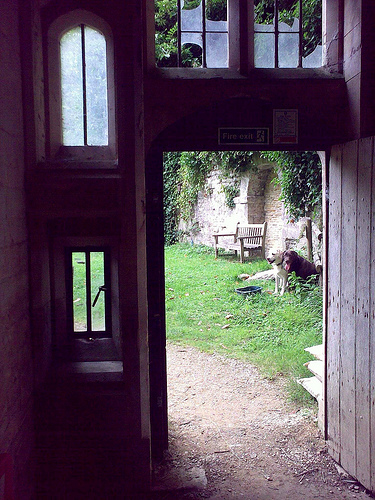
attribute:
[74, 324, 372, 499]
path — dirt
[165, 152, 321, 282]
wall — brick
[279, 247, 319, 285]
dog — brown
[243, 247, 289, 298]
dog — white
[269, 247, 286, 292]
dog — black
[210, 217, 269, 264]
bench — wooden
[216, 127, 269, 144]
sign — fire exit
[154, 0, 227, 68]
glass — broken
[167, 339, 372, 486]
path — dirt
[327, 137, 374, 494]
structure — wood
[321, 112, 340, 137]
ground — closed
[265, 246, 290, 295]
canine — white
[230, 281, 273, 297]
container — black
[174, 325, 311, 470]
path — dirt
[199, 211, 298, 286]
bench — wooden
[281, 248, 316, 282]
canine — dark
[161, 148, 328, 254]
plant — green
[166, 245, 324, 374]
terrain — green, grassy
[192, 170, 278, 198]
wall — brick, stone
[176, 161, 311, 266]
wall — brick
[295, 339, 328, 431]
steps — wooden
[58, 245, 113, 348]
window — small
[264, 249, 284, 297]
dog — white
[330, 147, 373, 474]
board wall — wooden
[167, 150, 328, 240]
plants — hanging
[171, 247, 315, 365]
space — green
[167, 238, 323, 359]
space — green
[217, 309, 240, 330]
leaves — brown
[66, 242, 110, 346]
window — rectangular